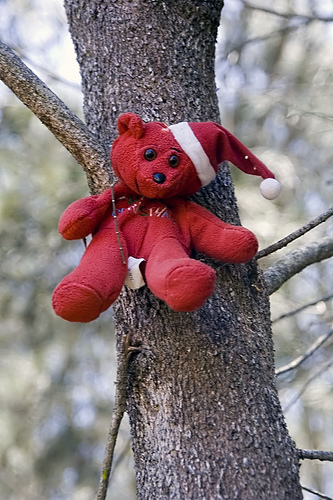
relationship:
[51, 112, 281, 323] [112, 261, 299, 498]
doll hanging on tree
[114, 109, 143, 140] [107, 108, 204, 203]
ear on side of head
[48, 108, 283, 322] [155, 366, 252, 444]
bear against trunk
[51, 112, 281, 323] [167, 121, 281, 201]
doll has hat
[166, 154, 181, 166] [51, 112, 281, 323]
eye on doll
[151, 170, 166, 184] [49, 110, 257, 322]
nose on teddy bear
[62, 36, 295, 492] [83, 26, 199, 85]
bark on trunk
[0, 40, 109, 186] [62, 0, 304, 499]
branch extended from trunk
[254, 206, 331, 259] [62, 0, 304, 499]
branch extended from trunk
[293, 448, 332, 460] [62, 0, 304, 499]
branch extended from trunk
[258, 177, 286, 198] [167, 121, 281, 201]
puff from hat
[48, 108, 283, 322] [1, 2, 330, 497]
bear attached to tree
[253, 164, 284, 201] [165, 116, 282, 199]
tip of hat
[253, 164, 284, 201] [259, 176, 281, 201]
tip has ball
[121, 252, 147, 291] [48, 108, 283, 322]
tag on bear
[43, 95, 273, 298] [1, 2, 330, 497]
doll hanged on tree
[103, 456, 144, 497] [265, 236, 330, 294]
snow on branches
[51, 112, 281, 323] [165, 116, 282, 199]
doll with hat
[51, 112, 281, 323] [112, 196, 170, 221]
doll with writing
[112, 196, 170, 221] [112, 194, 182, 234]
writing on chest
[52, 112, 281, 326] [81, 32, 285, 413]
bear nailed to tree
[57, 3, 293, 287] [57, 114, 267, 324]
tree with bear